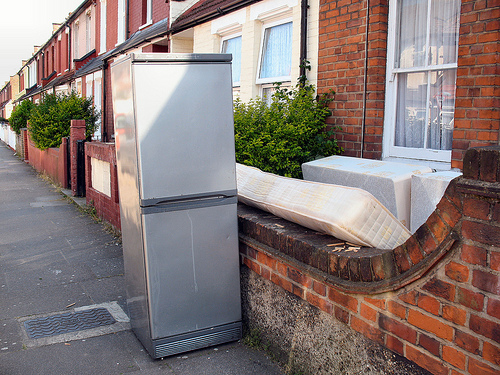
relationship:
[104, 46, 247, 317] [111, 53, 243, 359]
refrigerator refrigerator appliance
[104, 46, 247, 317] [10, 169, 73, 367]
appliance on sidewalk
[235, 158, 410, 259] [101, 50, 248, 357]
mattress beside appliance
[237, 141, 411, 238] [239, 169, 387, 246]
box springs beside mattress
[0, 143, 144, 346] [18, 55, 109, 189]
sidewalk in front of buildings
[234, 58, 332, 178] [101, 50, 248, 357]
green plants to left of appliance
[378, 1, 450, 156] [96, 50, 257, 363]
windows behind appliance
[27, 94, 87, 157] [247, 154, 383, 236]
planter in area of mattress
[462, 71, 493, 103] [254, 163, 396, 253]
bricks behind mattress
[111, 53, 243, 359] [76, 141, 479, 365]
appliance by wall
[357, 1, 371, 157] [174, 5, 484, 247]
pipe going up building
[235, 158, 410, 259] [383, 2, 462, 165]
mattress outside window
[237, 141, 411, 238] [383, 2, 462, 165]
box springs outside window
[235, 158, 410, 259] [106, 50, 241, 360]
mattress near refrigerator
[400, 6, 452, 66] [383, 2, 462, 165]
curtains in window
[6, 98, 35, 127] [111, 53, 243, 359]
bush behind appliance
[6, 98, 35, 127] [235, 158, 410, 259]
bush behind mattress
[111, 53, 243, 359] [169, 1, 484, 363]
appliance outside of building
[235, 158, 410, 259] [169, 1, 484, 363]
mattress outside of building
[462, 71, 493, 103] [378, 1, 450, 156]
bricks around windows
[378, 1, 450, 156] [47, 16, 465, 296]
windows around building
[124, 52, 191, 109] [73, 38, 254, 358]
corner on refrigerator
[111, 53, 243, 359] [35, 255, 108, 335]
appliance on sidewalk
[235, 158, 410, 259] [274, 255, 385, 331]
mattress behind wall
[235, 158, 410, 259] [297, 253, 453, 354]
mattress behind wall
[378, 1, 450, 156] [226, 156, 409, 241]
windows behind matresses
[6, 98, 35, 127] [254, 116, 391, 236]
bush behind matresses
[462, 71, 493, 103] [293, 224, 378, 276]
bricks on wall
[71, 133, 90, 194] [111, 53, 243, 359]
gate behind appliance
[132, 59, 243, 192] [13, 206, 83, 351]
door in sidewalk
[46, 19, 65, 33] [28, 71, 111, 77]
chimney on house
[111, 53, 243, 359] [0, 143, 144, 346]
appliance on sidewalk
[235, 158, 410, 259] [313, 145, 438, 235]
mattress and box spring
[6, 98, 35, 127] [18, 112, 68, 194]
bush in an enclosure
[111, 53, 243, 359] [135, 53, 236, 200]
appliance has door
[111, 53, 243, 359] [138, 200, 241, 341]
appliance has door